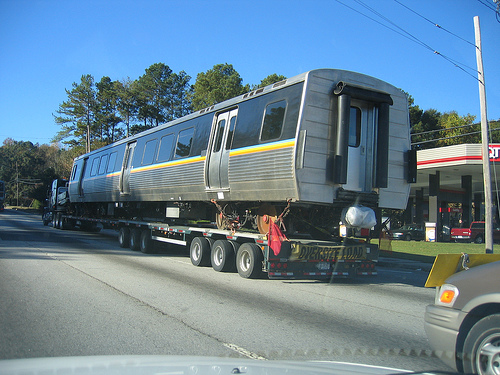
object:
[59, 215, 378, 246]
flatbed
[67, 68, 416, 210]
train car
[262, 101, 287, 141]
window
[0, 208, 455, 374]
road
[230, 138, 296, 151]
stripe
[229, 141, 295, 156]
stripe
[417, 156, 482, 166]
stripe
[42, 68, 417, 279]
car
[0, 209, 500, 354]
ground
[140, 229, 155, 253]
wheel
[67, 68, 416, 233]
train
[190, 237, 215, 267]
vase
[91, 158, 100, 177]
window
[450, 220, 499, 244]
red truck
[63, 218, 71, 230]
wheel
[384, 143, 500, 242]
gas station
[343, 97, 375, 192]
door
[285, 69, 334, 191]
back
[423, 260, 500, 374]
car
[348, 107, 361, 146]
window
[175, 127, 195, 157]
window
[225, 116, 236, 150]
window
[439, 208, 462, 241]
gas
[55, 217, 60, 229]
wheel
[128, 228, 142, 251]
wheel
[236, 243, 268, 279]
wheel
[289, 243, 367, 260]
sign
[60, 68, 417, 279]
trailer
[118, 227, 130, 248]
wheel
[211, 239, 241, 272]
wheel